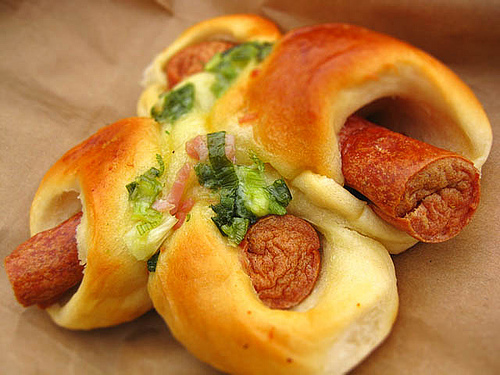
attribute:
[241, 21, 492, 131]
buns — sliced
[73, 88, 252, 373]
buns — sliced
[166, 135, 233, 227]
tomato — small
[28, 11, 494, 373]
buns — golden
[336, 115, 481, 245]
hot dog — split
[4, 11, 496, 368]
kitchen creation — new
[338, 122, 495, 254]
hotdog — sliced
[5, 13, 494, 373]
food — unique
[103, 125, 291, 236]
garnish — green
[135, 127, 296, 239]
garnish — green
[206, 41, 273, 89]
garnish — green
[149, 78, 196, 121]
garnish — green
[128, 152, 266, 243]
garnish — pink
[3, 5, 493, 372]
dish — fancy